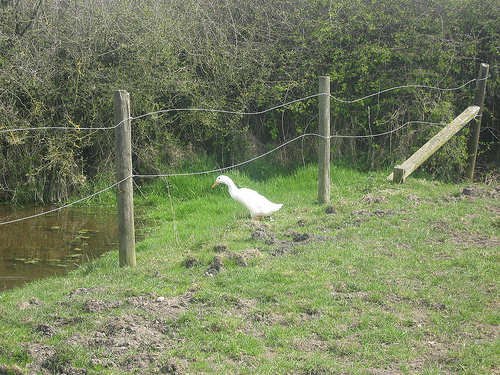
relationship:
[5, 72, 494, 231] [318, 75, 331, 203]
barbed wire on pole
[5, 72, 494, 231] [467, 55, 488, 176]
barbed wire on post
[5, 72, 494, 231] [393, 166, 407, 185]
barbed wire on pole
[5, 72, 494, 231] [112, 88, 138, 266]
barbed wire on fence pole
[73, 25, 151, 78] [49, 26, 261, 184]
limbs on tree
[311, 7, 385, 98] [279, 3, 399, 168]
tree with limbs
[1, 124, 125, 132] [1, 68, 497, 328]
wire of fence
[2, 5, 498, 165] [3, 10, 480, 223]
branches of trees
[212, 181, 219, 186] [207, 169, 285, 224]
beak of duck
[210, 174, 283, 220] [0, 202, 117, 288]
duck looking into water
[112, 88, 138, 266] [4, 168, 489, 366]
fence pole in grass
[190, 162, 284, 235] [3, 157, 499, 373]
duck standing in grass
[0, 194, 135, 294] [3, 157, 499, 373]
dirty water beside grass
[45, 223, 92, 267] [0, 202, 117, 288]
leaves floating on water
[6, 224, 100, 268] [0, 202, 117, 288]
leaves floating on water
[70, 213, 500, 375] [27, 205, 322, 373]
patch of grass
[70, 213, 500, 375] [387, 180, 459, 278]
patch of grass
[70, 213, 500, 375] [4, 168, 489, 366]
patch of grass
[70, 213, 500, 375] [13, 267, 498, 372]
patch of grass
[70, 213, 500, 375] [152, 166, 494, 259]
patch of grass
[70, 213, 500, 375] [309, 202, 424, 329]
patch of grass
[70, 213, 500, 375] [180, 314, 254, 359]
patch of grass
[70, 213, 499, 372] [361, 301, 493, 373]
patch of grass